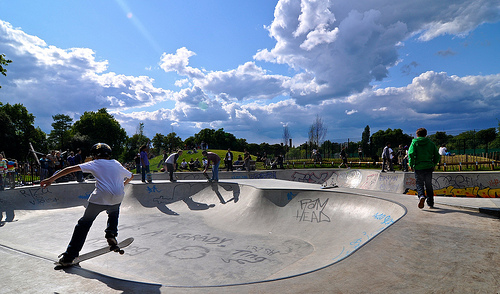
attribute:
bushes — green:
[272, 123, 491, 159]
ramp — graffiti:
[244, 187, 410, 292]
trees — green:
[5, 101, 132, 158]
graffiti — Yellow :
[409, 179, 495, 204]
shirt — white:
[74, 152, 131, 213]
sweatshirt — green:
[404, 136, 441, 173]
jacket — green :
[401, 134, 451, 166]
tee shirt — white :
[78, 156, 128, 202]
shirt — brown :
[176, 150, 248, 184]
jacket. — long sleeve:
[400, 125, 458, 201]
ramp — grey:
[5, 169, 478, 289]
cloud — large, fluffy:
[266, 0, 484, 93]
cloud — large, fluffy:
[11, 34, 151, 108]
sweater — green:
[407, 134, 443, 174]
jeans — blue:
[61, 203, 122, 247]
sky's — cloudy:
[273, 27, 349, 90]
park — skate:
[86, 68, 458, 271]